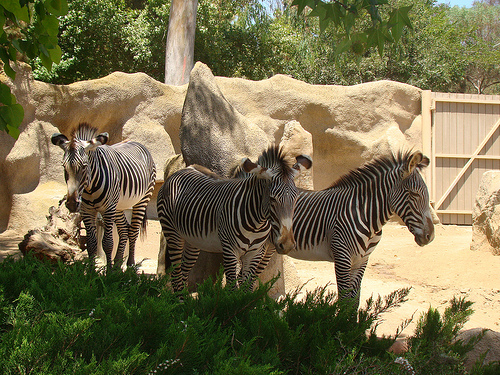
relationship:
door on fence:
[428, 91, 498, 226] [2, 63, 430, 232]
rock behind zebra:
[178, 60, 270, 178] [154, 141, 299, 294]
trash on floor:
[366, 339, 443, 360] [351, 327, 476, 369]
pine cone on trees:
[151, 361, 198, 373] [212, 5, 499, 107]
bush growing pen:
[5, 252, 497, 372] [15, 96, 472, 343]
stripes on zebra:
[180, 187, 262, 237] [282, 142, 436, 325]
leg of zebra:
[331, 261, 356, 308] [334, 150, 439, 252]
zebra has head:
[61, 126, 158, 270] [46, 126, 112, 211]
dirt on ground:
[394, 267, 442, 291] [385, 232, 498, 324]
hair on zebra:
[325, 143, 415, 190] [249, 149, 436, 324]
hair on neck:
[325, 143, 415, 190] [355, 160, 395, 240]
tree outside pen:
[165, 0, 198, 85] [1, 60, 498, 373]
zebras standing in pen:
[50, 120, 155, 271] [1, 60, 498, 373]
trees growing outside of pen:
[209, 7, 496, 77] [1, 60, 498, 373]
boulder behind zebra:
[0, 57, 440, 260] [51, 122, 156, 274]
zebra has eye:
[154, 146, 311, 285] [261, 193, 284, 212]